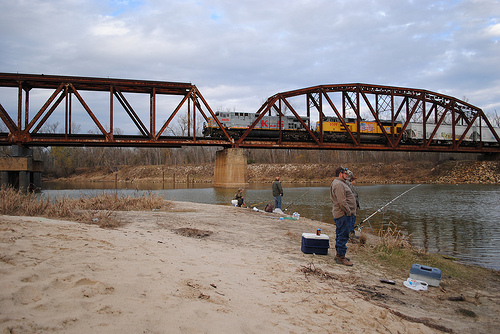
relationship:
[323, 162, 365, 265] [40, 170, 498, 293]
man side lake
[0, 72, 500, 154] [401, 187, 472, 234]
bridge crossing river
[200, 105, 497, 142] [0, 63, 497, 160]
train on bridge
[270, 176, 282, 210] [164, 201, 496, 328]
man standing on shore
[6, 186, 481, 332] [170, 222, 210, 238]
sand along dirt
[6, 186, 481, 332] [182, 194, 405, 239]
sand along shoreline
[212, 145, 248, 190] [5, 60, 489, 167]
support under bridge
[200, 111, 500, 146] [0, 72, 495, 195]
train over bridge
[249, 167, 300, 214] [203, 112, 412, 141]
man looking at train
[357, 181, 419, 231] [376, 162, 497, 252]
pole on side of lake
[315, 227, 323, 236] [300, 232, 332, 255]
can on cooler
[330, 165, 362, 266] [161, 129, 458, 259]
man in lake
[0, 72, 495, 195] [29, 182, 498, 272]
bridge over lake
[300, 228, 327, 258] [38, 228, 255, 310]
cooler on ground